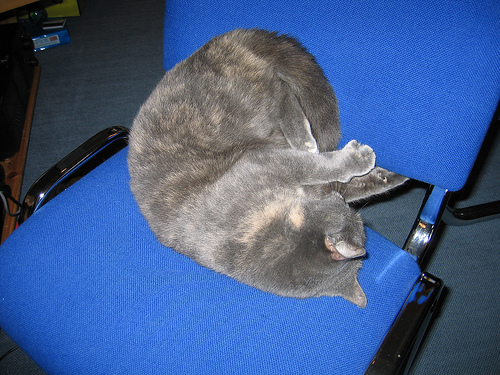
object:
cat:
[123, 27, 409, 308]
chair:
[0, 0, 500, 375]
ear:
[323, 232, 367, 261]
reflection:
[411, 229, 432, 246]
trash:
[31, 29, 73, 52]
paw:
[335, 139, 377, 184]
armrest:
[20, 123, 133, 226]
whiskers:
[322, 172, 355, 197]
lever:
[441, 200, 500, 226]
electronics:
[0, 36, 33, 159]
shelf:
[0, 62, 40, 246]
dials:
[22, 37, 39, 66]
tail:
[246, 29, 342, 152]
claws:
[382, 176, 388, 183]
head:
[278, 188, 369, 310]